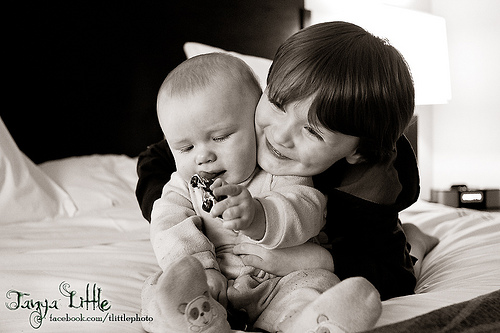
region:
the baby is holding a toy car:
[153, 162, 268, 238]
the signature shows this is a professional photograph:
[6, 264, 163, 329]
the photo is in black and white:
[9, 11, 496, 328]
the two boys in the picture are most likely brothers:
[83, 13, 433, 332]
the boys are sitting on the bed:
[15, 15, 485, 323]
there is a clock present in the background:
[440, 167, 490, 224]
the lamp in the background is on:
[352, 2, 463, 114]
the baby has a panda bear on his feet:
[170, 287, 225, 331]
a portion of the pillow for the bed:
[1, 122, 91, 244]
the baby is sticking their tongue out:
[190, 169, 225, 189]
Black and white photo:
[4, 8, 496, 329]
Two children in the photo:
[72, 4, 458, 326]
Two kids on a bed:
[109, 27, 461, 314]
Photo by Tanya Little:
[1, 282, 132, 310]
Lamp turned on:
[353, 9, 467, 141]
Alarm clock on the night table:
[428, 177, 496, 218]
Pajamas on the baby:
[123, 167, 388, 326]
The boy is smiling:
[239, 116, 326, 176]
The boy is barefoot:
[397, 222, 461, 266]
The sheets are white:
[0, 195, 492, 296]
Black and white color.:
[8, 11, 491, 323]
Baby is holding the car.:
[160, 146, 255, 241]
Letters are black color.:
[5, 280, 157, 325]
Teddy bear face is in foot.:
[171, 285, 221, 330]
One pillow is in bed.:
[6, 135, 81, 225]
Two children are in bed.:
[115, 12, 420, 315]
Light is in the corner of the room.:
[382, 12, 458, 98]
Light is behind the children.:
[347, 8, 449, 121]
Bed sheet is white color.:
[38, 190, 140, 291]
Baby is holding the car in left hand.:
[180, 157, 283, 235]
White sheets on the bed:
[54, 237, 99, 280]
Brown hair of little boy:
[310, 36, 344, 63]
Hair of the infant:
[175, 65, 202, 84]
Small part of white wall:
[462, 115, 479, 136]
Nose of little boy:
[275, 128, 290, 147]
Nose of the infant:
[192, 150, 218, 165]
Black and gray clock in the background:
[443, 189, 498, 206]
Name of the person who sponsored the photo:
[4, 287, 113, 311]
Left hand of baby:
[215, 188, 263, 239]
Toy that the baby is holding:
[193, 175, 213, 212]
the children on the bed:
[136, 20, 440, 332]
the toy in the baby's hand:
[188, 170, 225, 220]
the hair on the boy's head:
[267, 21, 415, 174]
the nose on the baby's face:
[193, 141, 215, 166]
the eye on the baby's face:
[211, 130, 235, 144]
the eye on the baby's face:
[175, 140, 194, 153]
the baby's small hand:
[207, 176, 254, 231]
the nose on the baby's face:
[273, 113, 301, 147]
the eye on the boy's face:
[301, 124, 326, 144]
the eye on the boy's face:
[266, 98, 286, 113]